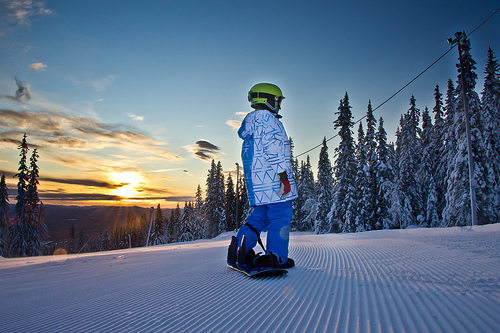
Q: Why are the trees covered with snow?
A: It's Cold.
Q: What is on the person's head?
A: A helmet.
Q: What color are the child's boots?
A: Black.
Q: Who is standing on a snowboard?
A: A child.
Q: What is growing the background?
A: Pine trees.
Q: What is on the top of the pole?
A: A light.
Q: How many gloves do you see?
A: One.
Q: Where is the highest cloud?
A: Upper left corner.